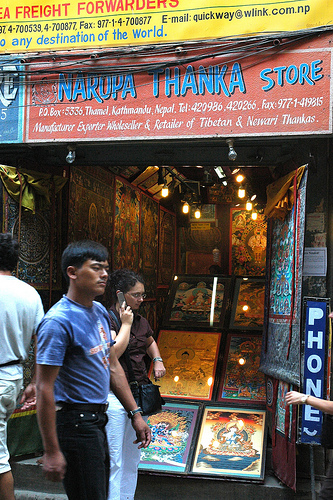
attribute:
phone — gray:
[116, 290, 130, 314]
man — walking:
[33, 243, 148, 500]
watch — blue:
[127, 406, 144, 419]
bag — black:
[126, 371, 162, 414]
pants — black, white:
[54, 401, 113, 496]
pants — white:
[107, 393, 143, 498]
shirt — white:
[2, 277, 44, 367]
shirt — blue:
[34, 297, 117, 404]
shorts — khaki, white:
[1, 364, 24, 474]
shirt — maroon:
[109, 312, 153, 383]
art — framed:
[139, 276, 272, 477]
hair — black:
[107, 272, 141, 292]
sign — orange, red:
[27, 47, 328, 138]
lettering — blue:
[61, 61, 329, 95]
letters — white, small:
[30, 95, 325, 131]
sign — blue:
[303, 299, 325, 443]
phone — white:
[307, 310, 319, 422]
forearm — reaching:
[288, 392, 330, 417]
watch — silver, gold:
[300, 393, 310, 406]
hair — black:
[2, 236, 20, 270]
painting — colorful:
[200, 406, 266, 479]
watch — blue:
[149, 356, 165, 363]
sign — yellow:
[4, 0, 331, 45]